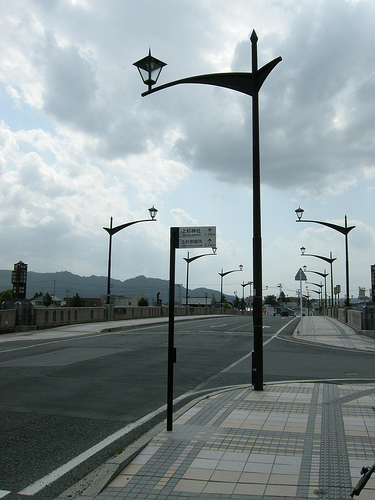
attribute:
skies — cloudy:
[14, 8, 372, 197]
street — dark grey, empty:
[12, 236, 325, 497]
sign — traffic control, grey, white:
[166, 209, 229, 265]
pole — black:
[158, 219, 191, 446]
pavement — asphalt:
[1, 312, 183, 456]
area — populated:
[24, 283, 239, 342]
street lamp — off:
[135, 28, 312, 403]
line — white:
[13, 393, 180, 500]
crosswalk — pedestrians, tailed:
[297, 303, 372, 358]